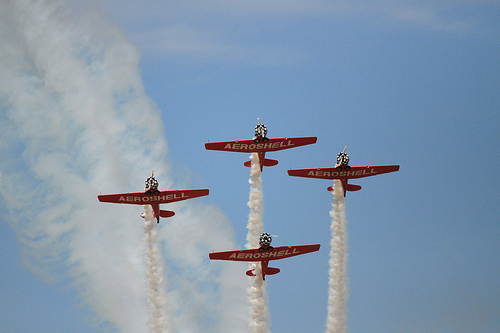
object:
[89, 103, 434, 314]
plains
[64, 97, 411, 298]
formation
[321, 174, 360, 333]
trail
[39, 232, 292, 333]
cloud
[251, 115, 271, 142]
propeller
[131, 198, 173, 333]
smoke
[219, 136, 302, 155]
aeroshell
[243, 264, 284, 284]
tail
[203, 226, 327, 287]
airplane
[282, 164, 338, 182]
wings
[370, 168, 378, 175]
letters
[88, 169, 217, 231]
plane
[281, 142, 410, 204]
plane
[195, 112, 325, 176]
plane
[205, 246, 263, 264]
wing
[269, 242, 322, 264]
wing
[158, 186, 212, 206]
wing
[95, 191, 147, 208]
wing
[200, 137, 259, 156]
wing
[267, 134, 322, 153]
wing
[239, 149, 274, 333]
trails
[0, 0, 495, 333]
sky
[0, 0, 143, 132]
clouds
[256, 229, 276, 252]
propeller